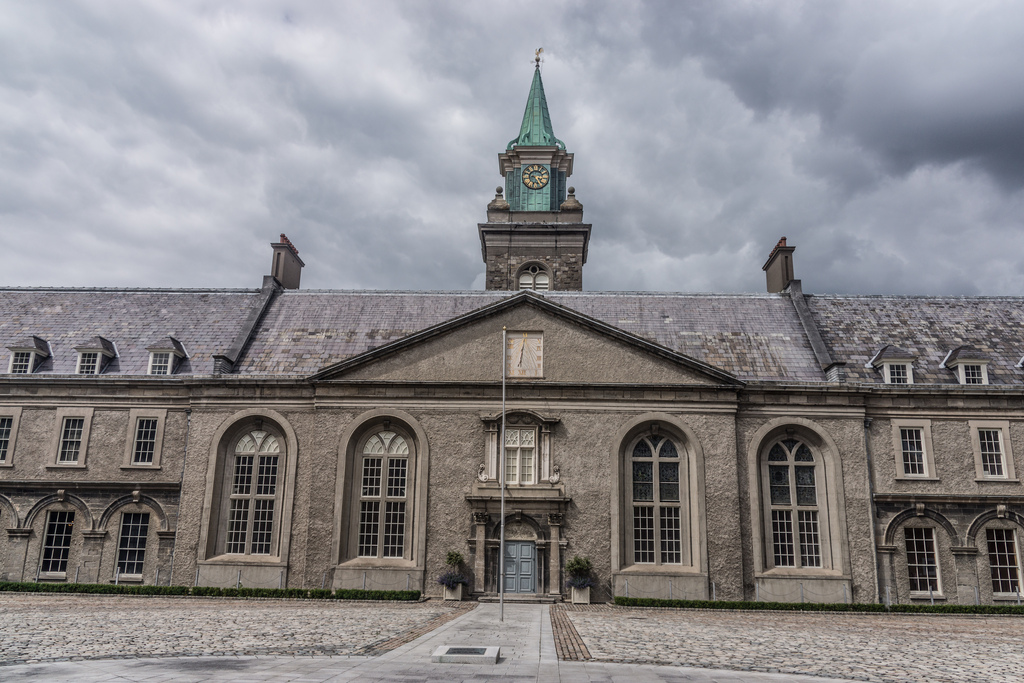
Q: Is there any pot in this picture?
A: Yes, there is a pot.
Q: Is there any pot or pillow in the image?
A: Yes, there is a pot.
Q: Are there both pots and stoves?
A: No, there is a pot but no stoves.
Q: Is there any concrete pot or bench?
A: Yes, there is a concrete pot.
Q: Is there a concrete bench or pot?
A: Yes, there is a concrete pot.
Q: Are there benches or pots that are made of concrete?
A: Yes, the pot is made of concrete.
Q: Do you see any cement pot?
A: Yes, there is a pot that is made of cement.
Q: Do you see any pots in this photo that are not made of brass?
A: Yes, there is a pot that is made of cement.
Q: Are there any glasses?
A: No, there are no glasses.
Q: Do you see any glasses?
A: No, there are no glasses.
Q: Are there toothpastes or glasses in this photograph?
A: No, there are no glasses or toothpastes.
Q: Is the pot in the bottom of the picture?
A: Yes, the pot is in the bottom of the image.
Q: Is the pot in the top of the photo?
A: No, the pot is in the bottom of the image.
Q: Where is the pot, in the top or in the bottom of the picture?
A: The pot is in the bottom of the image.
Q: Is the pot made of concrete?
A: Yes, the pot is made of concrete.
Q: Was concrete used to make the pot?
A: Yes, the pot is made of concrete.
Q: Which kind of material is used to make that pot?
A: The pot is made of concrete.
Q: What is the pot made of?
A: The pot is made of concrete.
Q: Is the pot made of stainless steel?
A: No, the pot is made of cement.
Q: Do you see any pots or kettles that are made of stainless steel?
A: No, there is a pot but it is made of concrete.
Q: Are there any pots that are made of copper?
A: No, there is a pot but it is made of cement.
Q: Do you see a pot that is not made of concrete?
A: No, there is a pot but it is made of concrete.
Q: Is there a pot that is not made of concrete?
A: No, there is a pot but it is made of concrete.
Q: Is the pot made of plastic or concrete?
A: The pot is made of concrete.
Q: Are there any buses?
A: No, there are no buses.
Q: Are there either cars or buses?
A: No, there are no buses or cars.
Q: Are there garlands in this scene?
A: No, there are no garlands.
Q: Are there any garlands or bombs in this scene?
A: No, there are no garlands or bombs.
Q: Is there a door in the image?
A: Yes, there is a door.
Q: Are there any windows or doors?
A: Yes, there is a door.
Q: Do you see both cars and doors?
A: No, there is a door but no cars.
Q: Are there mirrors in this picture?
A: No, there are no mirrors.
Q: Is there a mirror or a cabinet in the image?
A: No, there are no mirrors or cabinets.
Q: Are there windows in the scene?
A: Yes, there is a window.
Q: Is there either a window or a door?
A: Yes, there is a window.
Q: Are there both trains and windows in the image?
A: No, there is a window but no trains.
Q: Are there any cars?
A: No, there are no cars.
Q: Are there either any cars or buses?
A: No, there are no cars or buses.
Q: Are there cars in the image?
A: No, there are no cars.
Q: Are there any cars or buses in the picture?
A: No, there are no cars or buses.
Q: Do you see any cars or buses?
A: No, there are no cars or buses.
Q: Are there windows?
A: Yes, there is a window.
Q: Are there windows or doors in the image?
A: Yes, there is a window.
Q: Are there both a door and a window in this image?
A: Yes, there are both a window and a door.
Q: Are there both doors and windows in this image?
A: Yes, there are both a window and a door.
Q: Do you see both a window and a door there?
A: Yes, there are both a window and a door.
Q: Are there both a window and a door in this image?
A: Yes, there are both a window and a door.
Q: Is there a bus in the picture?
A: No, there are no buses.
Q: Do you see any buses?
A: No, there are no buses.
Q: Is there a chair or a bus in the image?
A: No, there are no buses or chairs.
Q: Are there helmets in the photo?
A: No, there are no helmets.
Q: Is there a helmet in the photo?
A: No, there are no helmets.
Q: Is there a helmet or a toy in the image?
A: No, there are no helmets or toys.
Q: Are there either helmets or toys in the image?
A: No, there are no helmets or toys.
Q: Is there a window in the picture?
A: Yes, there is a window.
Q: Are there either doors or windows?
A: Yes, there is a window.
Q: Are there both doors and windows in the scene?
A: Yes, there are both a window and a door.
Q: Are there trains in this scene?
A: No, there are no trains.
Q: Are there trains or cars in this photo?
A: No, there are no trains or cars.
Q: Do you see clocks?
A: Yes, there is a clock.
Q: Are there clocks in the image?
A: Yes, there is a clock.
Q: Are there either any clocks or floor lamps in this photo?
A: Yes, there is a clock.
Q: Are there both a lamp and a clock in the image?
A: No, there is a clock but no lamps.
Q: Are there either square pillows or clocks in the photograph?
A: Yes, there is a square clock.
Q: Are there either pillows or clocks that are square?
A: Yes, the clock is square.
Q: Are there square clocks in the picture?
A: Yes, there is a square clock.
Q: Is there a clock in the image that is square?
A: Yes, there is a clock that is square.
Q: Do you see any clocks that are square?
A: Yes, there is a clock that is square.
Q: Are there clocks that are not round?
A: Yes, there is a square clock.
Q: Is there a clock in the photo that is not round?
A: Yes, there is a square clock.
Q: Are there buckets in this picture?
A: No, there are no buckets.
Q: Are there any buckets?
A: No, there are no buckets.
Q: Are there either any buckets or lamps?
A: No, there are no buckets or lamps.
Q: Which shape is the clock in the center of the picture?
A: The clock is square.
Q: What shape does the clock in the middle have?
A: The clock has square shape.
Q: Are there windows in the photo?
A: Yes, there is a window.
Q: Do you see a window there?
A: Yes, there is a window.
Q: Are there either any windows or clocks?
A: Yes, there is a window.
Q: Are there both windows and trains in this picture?
A: No, there is a window but no trains.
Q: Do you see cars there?
A: No, there are no cars.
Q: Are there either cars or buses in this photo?
A: No, there are no cars or buses.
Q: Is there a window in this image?
A: Yes, there is a window.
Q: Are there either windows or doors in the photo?
A: Yes, there is a window.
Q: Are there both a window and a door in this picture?
A: Yes, there are both a window and a door.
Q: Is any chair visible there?
A: No, there are no chairs.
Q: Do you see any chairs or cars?
A: No, there are no chairs or cars.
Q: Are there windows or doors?
A: Yes, there is a window.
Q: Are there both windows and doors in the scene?
A: Yes, there are both a window and a door.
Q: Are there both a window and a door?
A: Yes, there are both a window and a door.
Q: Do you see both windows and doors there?
A: Yes, there are both a window and a door.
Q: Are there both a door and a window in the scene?
A: Yes, there are both a window and a door.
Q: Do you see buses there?
A: No, there are no buses.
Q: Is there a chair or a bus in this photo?
A: No, there are no buses or chairs.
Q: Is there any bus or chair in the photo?
A: No, there are no buses or chairs.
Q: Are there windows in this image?
A: Yes, there is a window.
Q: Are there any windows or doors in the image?
A: Yes, there is a window.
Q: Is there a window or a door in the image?
A: Yes, there is a window.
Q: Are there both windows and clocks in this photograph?
A: Yes, there are both a window and a clock.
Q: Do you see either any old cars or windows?
A: Yes, there is an old window.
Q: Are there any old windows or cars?
A: Yes, there is an old window.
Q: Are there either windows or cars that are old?
A: Yes, the window is old.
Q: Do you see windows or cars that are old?
A: Yes, the window is old.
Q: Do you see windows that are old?
A: Yes, there is an old window.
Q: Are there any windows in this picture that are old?
A: Yes, there is a window that is old.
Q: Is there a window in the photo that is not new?
A: Yes, there is a old window.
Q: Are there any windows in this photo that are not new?
A: Yes, there is a old window.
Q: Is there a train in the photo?
A: No, there are no trains.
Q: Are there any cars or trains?
A: No, there are no trains or cars.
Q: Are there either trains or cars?
A: No, there are no trains or cars.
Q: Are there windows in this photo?
A: Yes, there is a window.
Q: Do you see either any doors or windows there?
A: Yes, there is a window.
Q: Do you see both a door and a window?
A: Yes, there are both a window and a door.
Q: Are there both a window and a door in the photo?
A: Yes, there are both a window and a door.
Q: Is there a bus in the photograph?
A: No, there are no buses.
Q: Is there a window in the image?
A: Yes, there is a window.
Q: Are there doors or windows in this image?
A: Yes, there is a window.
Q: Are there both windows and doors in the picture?
A: Yes, there are both a window and a door.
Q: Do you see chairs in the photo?
A: No, there are no chairs.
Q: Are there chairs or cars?
A: No, there are no chairs or cars.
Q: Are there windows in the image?
A: Yes, there is a window.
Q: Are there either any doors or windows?
A: Yes, there is a window.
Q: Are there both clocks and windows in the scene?
A: Yes, there are both a window and a clock.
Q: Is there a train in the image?
A: No, there are no trains.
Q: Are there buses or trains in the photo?
A: No, there are no trains or buses.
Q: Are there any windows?
A: Yes, there is a window.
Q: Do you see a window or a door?
A: Yes, there is a window.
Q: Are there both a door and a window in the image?
A: Yes, there are both a window and a door.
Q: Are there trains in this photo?
A: No, there are no trains.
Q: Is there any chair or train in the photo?
A: No, there are no trains or chairs.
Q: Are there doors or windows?
A: Yes, there is a window.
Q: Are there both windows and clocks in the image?
A: Yes, there are both a window and a clock.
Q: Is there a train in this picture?
A: No, there are no trains.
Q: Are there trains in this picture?
A: No, there are no trains.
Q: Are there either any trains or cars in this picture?
A: No, there are no trains or cars.